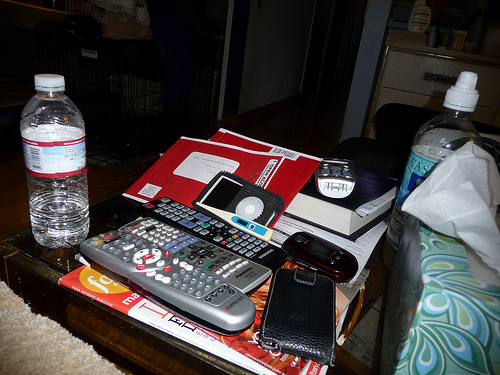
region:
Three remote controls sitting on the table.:
[132, 171, 276, 323]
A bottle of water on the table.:
[11, 103, 101, 280]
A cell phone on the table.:
[281, 217, 369, 292]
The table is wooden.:
[28, 247, 228, 374]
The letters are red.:
[176, 119, 324, 213]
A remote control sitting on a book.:
[302, 142, 399, 236]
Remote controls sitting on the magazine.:
[54, 252, 297, 367]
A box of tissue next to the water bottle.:
[395, 185, 499, 344]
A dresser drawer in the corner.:
[381, 51, 498, 112]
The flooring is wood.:
[283, 93, 338, 153]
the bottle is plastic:
[32, 69, 135, 225]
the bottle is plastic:
[9, 63, 264, 355]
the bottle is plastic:
[21, 81, 152, 301]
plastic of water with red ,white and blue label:
[20, 72, 94, 252]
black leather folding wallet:
[259, 263, 339, 364]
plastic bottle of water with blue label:
[390, 71, 485, 245]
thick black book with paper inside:
[273, 130, 400, 242]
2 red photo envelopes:
[119, 127, 329, 244]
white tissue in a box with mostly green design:
[380, 151, 499, 373]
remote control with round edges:
[78, 227, 258, 338]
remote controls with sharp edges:
[121, 194, 287, 290]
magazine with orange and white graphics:
[56, 202, 370, 374]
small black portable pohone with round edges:
[282, 226, 361, 285]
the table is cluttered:
[2, 90, 398, 370]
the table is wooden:
[11, 110, 396, 370]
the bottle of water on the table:
[12, 55, 92, 250]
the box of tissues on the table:
[370, 201, 495, 371]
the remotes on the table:
[81, 195, 272, 327]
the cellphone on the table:
[277, 225, 367, 280]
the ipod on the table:
[185, 150, 290, 215]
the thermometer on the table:
[190, 195, 270, 235]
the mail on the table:
[130, 115, 340, 220]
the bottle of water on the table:
[381, 66, 486, 283]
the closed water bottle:
[20, 70, 91, 247]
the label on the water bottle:
[14, 122, 88, 177]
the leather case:
[260, 260, 337, 358]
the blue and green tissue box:
[373, 203, 488, 371]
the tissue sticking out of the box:
[415, 143, 499, 256]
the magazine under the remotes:
[57, 223, 342, 368]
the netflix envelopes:
[120, 120, 317, 229]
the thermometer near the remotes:
[191, 200, 276, 242]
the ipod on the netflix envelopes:
[197, 170, 282, 228]